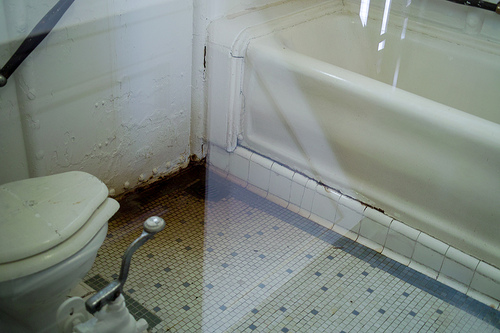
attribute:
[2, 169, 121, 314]
seat — toilet, damaged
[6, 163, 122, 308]
seat — toilet, cracked, discolored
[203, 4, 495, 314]
bathtub — white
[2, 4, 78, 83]
bar — black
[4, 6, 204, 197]
wall — white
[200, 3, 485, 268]
tub — white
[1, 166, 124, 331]
toilet — white, off-white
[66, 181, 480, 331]
tiles — white, small, square, floor tiles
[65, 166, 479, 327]
floor — patterned, tiled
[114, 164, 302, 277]
stain — rust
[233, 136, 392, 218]
crack — forming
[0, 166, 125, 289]
toilet seat — worn out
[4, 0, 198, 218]
wall — white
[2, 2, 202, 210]
paint — damaged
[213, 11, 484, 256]
tub — white